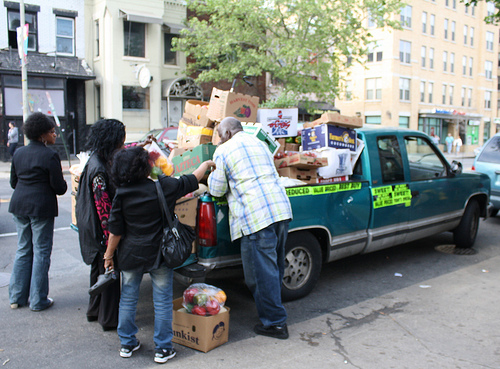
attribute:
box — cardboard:
[207, 86, 261, 120]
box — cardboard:
[258, 106, 302, 139]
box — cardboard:
[307, 111, 364, 131]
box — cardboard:
[297, 120, 360, 154]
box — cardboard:
[274, 151, 331, 172]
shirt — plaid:
[207, 131, 293, 241]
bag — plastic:
[183, 284, 226, 315]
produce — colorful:
[187, 287, 218, 312]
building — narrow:
[186, 3, 267, 99]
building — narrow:
[1, 2, 188, 161]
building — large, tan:
[334, 1, 499, 153]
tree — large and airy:
[184, 55, 353, 114]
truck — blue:
[291, 204, 365, 232]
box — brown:
[193, 328, 211, 336]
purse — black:
[162, 225, 192, 258]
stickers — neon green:
[285, 187, 334, 192]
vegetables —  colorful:
[191, 290, 223, 339]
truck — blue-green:
[135, 112, 489, 354]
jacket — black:
[70, 189, 93, 233]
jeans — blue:
[255, 226, 295, 299]